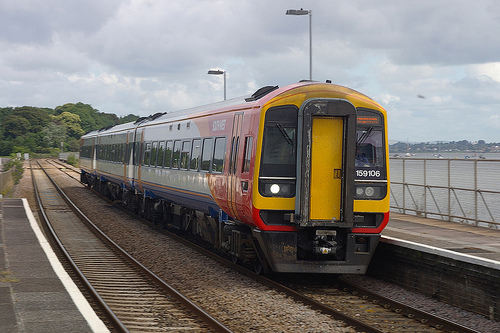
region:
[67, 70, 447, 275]
A 3 car passenger train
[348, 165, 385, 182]
The identifying number of the train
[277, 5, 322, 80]
An overhead light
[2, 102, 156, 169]
A treeline in the behing the train tracks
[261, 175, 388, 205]
headlights on the train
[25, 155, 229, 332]
Empty train tracks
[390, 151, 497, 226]
A small body of water next to the train tracks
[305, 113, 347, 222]
The yellow door into the train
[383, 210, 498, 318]
A walkway next to train tracks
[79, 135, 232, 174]
Windows for the passengers to see out of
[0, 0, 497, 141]
cloud cover in sky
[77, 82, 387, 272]
yellow front of train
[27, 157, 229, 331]
two rails of train tracks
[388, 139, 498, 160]
land above water on horizon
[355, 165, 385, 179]
white numbers on black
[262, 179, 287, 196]
glowing white circular light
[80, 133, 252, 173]
line of windows on train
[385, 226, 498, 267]
white line on platform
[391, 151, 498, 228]
body of calm water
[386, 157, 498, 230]
metal poles of fence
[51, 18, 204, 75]
sky covered with large grey and whie clouds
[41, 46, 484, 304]
train tracks by the ocean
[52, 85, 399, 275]
passenger train on train tracks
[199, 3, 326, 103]
two modern lights over train tracks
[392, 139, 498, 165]
boats in the ocean water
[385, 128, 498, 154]
town seen in the background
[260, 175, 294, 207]
one train headlight lit up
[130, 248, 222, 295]
gravel in between train tracks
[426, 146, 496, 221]
silver chain link fence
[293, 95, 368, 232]
yellow door on the front of train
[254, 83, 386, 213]
The yellow face of a train.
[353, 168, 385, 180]
A long number in white letters.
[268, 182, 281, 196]
A round white light.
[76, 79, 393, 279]
A train on the tracks.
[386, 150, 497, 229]
A view of the water.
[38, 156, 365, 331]
Gravel in between train tracks.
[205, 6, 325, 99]
The tops of two street lights.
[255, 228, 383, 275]
A black metal plate on the bottom front of a train.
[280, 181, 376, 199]
Three unlit lights.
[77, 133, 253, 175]
Windows on a train.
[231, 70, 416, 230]
front of the train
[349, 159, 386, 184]
number on the train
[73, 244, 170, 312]
track next to the train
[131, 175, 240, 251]
bottom part of train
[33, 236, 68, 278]
white line next to track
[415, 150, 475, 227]
fence next to train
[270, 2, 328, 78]
light next to the train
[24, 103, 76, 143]
trees in the distance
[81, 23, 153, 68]
cloud in the sky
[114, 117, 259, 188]
windows on side of the train